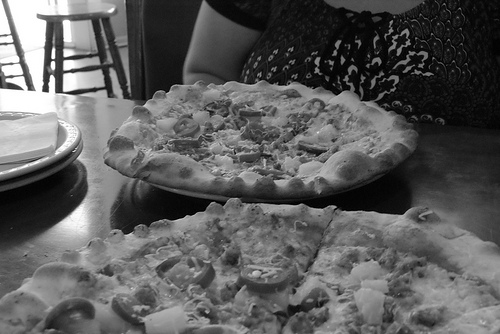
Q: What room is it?
A: It is a kitchen.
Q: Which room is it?
A: It is a kitchen.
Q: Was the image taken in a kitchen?
A: Yes, it was taken in a kitchen.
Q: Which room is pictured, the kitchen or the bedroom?
A: It is the kitchen.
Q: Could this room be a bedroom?
A: No, it is a kitchen.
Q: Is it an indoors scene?
A: Yes, it is indoors.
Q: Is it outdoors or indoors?
A: It is indoors.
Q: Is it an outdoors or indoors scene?
A: It is indoors.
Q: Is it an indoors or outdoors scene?
A: It is indoors.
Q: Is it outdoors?
A: No, it is indoors.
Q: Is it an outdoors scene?
A: No, it is indoors.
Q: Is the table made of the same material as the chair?
A: Yes, both the table and the chair are made of wood.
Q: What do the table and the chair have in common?
A: The material, both the table and the chair are wooden.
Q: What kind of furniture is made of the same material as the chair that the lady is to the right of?
A: The table is made of the same material as the chair.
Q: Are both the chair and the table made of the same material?
A: Yes, both the chair and the table are made of wood.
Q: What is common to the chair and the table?
A: The material, both the chair and the table are wooden.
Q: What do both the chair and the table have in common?
A: The material, both the chair and the table are wooden.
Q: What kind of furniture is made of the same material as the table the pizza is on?
A: The chair is made of the same material as the table.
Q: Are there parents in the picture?
A: No, there are no parents.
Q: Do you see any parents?
A: No, there are no parents.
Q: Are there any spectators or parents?
A: No, there are no parents or spectators.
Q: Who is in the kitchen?
A: The lady is in the kitchen.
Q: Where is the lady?
A: The lady is in the kitchen.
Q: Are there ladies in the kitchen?
A: Yes, there is a lady in the kitchen.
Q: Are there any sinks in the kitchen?
A: No, there is a lady in the kitchen.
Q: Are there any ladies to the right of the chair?
A: Yes, there is a lady to the right of the chair.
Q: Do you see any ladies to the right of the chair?
A: Yes, there is a lady to the right of the chair.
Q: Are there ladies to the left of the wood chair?
A: No, the lady is to the right of the chair.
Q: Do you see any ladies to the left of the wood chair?
A: No, the lady is to the right of the chair.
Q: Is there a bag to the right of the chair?
A: No, there is a lady to the right of the chair.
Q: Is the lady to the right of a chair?
A: Yes, the lady is to the right of a chair.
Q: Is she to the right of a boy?
A: No, the lady is to the right of a chair.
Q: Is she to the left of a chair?
A: No, the lady is to the right of a chair.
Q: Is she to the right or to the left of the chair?
A: The lady is to the right of the chair.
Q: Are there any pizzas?
A: Yes, there is a pizza.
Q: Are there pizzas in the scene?
A: Yes, there is a pizza.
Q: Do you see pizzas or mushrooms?
A: Yes, there is a pizza.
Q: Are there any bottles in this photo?
A: No, there are no bottles.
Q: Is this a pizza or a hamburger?
A: This is a pizza.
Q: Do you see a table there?
A: Yes, there is a table.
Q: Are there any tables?
A: Yes, there is a table.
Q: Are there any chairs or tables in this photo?
A: Yes, there is a table.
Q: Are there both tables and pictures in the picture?
A: No, there is a table but no pictures.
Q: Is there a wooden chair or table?
A: Yes, there is a wood table.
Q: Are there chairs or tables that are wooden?
A: Yes, the table is wooden.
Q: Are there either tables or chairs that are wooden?
A: Yes, the table is wooden.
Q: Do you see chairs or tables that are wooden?
A: Yes, the table is wooden.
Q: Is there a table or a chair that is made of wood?
A: Yes, the table is made of wood.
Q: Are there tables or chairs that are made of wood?
A: Yes, the table is made of wood.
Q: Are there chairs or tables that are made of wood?
A: Yes, the table is made of wood.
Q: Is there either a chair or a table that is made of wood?
A: Yes, the table is made of wood.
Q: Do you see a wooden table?
A: Yes, there is a wood table.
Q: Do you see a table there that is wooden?
A: Yes, there is a table that is wooden.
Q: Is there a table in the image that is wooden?
A: Yes, there is a table that is wooden.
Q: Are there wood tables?
A: Yes, there is a table that is made of wood.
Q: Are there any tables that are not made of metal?
A: Yes, there is a table that is made of wood.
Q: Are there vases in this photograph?
A: No, there are no vases.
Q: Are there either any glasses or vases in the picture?
A: No, there are no vases or glasses.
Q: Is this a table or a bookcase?
A: This is a table.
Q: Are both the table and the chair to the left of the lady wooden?
A: Yes, both the table and the chair are wooden.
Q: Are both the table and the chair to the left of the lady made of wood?
A: Yes, both the table and the chair are made of wood.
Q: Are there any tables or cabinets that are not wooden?
A: No, there is a table but it is wooden.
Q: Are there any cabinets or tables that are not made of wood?
A: No, there is a table but it is made of wood.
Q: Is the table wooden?
A: Yes, the table is wooden.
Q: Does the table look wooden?
A: Yes, the table is wooden.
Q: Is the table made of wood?
A: Yes, the table is made of wood.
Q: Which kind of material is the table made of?
A: The table is made of wood.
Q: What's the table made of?
A: The table is made of wood.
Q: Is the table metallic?
A: No, the table is wooden.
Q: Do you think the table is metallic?
A: No, the table is wooden.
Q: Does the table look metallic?
A: No, the table is wooden.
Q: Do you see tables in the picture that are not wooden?
A: No, there is a table but it is wooden.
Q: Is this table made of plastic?
A: No, the table is made of wood.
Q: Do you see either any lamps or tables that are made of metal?
A: No, there is a table but it is made of wood.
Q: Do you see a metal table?
A: No, there is a table but it is made of wood.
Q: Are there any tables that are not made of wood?
A: No, there is a table but it is made of wood.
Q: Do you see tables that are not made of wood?
A: No, there is a table but it is made of wood.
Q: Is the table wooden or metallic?
A: The table is wooden.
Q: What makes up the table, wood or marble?
A: The table is made of wood.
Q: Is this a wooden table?
A: Yes, this is a wooden table.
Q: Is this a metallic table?
A: No, this is a wooden table.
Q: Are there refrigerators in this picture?
A: No, there are no refrigerators.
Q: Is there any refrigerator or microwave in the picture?
A: No, there are no refrigerators or microwaves.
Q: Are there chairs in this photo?
A: Yes, there is a chair.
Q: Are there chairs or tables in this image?
A: Yes, there is a chair.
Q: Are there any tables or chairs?
A: Yes, there is a chair.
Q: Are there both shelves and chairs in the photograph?
A: No, there is a chair but no shelves.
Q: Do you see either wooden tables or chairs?
A: Yes, there is a wood chair.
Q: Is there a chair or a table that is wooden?
A: Yes, the chair is wooden.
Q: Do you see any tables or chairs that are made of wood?
A: Yes, the chair is made of wood.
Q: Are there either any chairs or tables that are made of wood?
A: Yes, the chair is made of wood.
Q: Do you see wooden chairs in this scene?
A: Yes, there is a wood chair.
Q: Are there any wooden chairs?
A: Yes, there is a wood chair.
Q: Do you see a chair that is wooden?
A: Yes, there is a chair that is wooden.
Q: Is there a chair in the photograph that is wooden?
A: Yes, there is a chair that is wooden.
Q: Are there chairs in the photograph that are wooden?
A: Yes, there is a chair that is wooden.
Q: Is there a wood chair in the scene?
A: Yes, there is a chair that is made of wood.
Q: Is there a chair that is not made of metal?
A: Yes, there is a chair that is made of wood.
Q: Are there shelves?
A: No, there are no shelves.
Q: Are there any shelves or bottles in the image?
A: No, there are no shelves or bottles.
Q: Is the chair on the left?
A: Yes, the chair is on the left of the image.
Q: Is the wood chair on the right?
A: No, the chair is on the left of the image.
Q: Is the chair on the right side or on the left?
A: The chair is on the left of the image.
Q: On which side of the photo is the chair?
A: The chair is on the left of the image.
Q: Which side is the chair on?
A: The chair is on the left of the image.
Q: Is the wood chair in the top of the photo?
A: Yes, the chair is in the top of the image.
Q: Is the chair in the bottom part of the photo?
A: No, the chair is in the top of the image.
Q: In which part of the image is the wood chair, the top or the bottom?
A: The chair is in the top of the image.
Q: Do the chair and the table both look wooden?
A: Yes, both the chair and the table are wooden.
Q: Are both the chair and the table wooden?
A: Yes, both the chair and the table are wooden.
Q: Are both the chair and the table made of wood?
A: Yes, both the chair and the table are made of wood.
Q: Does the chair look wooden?
A: Yes, the chair is wooden.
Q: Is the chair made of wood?
A: Yes, the chair is made of wood.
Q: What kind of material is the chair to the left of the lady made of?
A: The chair is made of wood.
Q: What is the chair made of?
A: The chair is made of wood.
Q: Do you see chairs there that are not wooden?
A: No, there is a chair but it is wooden.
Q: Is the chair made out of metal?
A: No, the chair is made of wood.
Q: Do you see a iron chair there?
A: No, there is a chair but it is made of wood.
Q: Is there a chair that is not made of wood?
A: No, there is a chair but it is made of wood.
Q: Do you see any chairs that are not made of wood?
A: No, there is a chair but it is made of wood.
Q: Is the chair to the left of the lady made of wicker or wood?
A: The chair is made of wood.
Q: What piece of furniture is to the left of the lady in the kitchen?
A: The piece of furniture is a chair.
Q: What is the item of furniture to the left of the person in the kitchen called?
A: The piece of furniture is a chair.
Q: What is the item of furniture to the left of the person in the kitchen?
A: The piece of furniture is a chair.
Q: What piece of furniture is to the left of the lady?
A: The piece of furniture is a chair.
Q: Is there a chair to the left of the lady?
A: Yes, there is a chair to the left of the lady.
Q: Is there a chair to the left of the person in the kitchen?
A: Yes, there is a chair to the left of the lady.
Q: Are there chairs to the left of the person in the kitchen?
A: Yes, there is a chair to the left of the lady.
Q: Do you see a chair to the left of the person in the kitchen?
A: Yes, there is a chair to the left of the lady.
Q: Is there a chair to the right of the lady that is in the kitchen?
A: No, the chair is to the left of the lady.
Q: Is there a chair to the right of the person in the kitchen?
A: No, the chair is to the left of the lady.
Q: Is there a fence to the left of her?
A: No, there is a chair to the left of the lady.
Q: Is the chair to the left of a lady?
A: Yes, the chair is to the left of a lady.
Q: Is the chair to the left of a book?
A: No, the chair is to the left of a lady.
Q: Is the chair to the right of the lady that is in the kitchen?
A: No, the chair is to the left of the lady.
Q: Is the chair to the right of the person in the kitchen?
A: No, the chair is to the left of the lady.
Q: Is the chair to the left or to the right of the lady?
A: The chair is to the left of the lady.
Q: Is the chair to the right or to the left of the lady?
A: The chair is to the left of the lady.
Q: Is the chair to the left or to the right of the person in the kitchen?
A: The chair is to the left of the lady.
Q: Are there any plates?
A: Yes, there is a plate.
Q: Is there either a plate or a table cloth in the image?
A: Yes, there is a plate.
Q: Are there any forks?
A: No, there are no forks.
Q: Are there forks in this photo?
A: No, there are no forks.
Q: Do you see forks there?
A: No, there are no forks.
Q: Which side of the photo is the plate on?
A: The plate is on the left of the image.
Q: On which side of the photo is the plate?
A: The plate is on the left of the image.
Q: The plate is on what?
A: The plate is on the table.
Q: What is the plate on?
A: The plate is on the table.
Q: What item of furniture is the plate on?
A: The plate is on the table.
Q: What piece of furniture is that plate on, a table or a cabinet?
A: The plate is on a table.